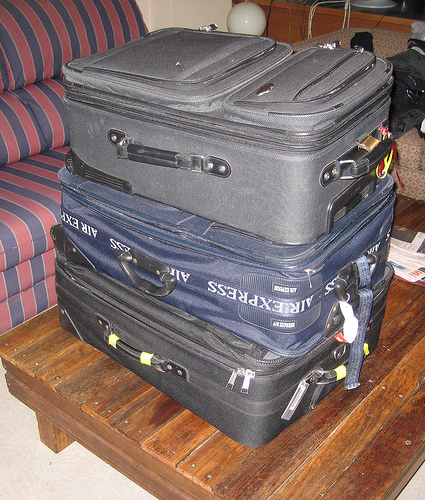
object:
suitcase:
[48, 220, 393, 452]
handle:
[106, 128, 231, 178]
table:
[0, 260, 425, 500]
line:
[29, 351, 62, 373]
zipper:
[288, 249, 318, 269]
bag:
[57, 172, 396, 356]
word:
[376, 148, 394, 180]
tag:
[375, 150, 393, 180]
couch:
[0, 0, 149, 329]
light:
[225, 4, 266, 35]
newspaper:
[378, 221, 425, 284]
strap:
[343, 290, 375, 392]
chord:
[342, 15, 347, 31]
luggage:
[65, 26, 396, 247]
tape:
[359, 135, 379, 153]